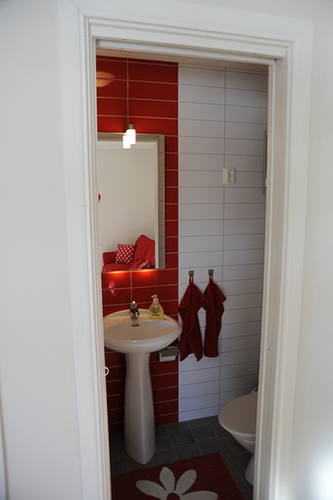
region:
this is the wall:
[184, 104, 251, 253]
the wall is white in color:
[198, 146, 232, 213]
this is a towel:
[204, 282, 225, 351]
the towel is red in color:
[206, 290, 226, 325]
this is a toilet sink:
[218, 391, 249, 452]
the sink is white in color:
[231, 396, 249, 421]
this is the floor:
[181, 430, 211, 447]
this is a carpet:
[178, 464, 219, 490]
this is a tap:
[127, 298, 142, 325]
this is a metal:
[127, 296, 147, 326]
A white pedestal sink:
[104, 299, 183, 465]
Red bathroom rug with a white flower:
[115, 451, 246, 498]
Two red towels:
[177, 270, 226, 362]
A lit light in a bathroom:
[119, 120, 140, 150]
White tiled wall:
[181, 69, 261, 266]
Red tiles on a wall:
[97, 59, 177, 123]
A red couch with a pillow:
[102, 231, 159, 268]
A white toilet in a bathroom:
[215, 392, 253, 485]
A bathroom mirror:
[96, 131, 164, 234]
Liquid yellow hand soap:
[146, 293, 165, 321]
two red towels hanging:
[168, 263, 241, 361]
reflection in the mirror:
[100, 128, 180, 274]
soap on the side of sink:
[145, 293, 173, 325]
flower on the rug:
[136, 467, 225, 498]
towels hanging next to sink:
[160, 262, 250, 378]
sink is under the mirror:
[107, 296, 190, 463]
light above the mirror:
[120, 123, 143, 151]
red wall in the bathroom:
[100, 67, 173, 271]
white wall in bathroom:
[186, 95, 264, 255]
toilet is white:
[222, 379, 276, 496]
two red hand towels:
[172, 255, 229, 372]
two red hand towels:
[184, 264, 252, 385]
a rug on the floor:
[118, 453, 230, 492]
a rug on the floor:
[124, 422, 219, 494]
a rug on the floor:
[147, 447, 209, 498]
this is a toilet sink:
[209, 387, 256, 453]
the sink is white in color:
[220, 404, 245, 428]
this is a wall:
[183, 113, 270, 265]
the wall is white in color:
[205, 196, 243, 223]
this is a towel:
[180, 282, 207, 346]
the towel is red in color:
[180, 299, 201, 328]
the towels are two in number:
[179, 279, 234, 365]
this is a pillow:
[114, 243, 133, 262]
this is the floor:
[181, 423, 224, 482]